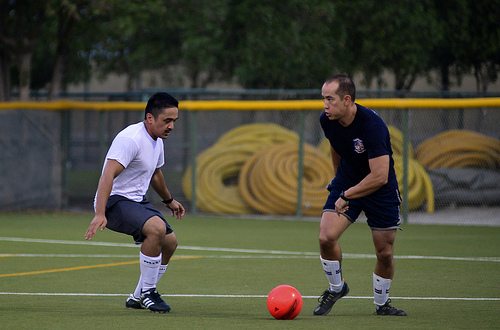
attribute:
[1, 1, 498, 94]
tree tops — behind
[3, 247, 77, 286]
lines — painted, yellow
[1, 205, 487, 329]
field — lined, turf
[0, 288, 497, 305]
lines — white, painted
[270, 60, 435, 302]
men — playing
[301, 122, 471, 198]
blue shirt — dark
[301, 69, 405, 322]
man — kicking